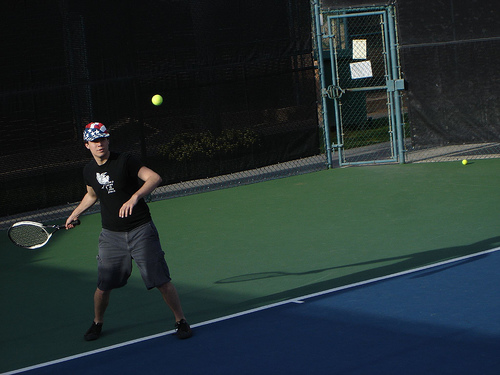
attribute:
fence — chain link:
[1, 3, 498, 234]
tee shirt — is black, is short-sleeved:
[84, 157, 153, 230]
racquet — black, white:
[2, 183, 93, 265]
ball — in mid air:
[151, 94, 163, 106]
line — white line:
[13, 243, 498, 374]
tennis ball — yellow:
[140, 84, 173, 116]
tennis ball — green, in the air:
[148, 92, 165, 107]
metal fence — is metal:
[323, 2, 398, 171]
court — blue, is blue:
[3, 161, 499, 373]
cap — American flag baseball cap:
[81, 121, 113, 141]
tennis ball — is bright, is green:
[152, 93, 162, 104]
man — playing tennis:
[54, 122, 197, 340]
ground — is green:
[5, 154, 497, 371]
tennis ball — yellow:
[457, 156, 472, 168]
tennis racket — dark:
[3, 211, 77, 266]